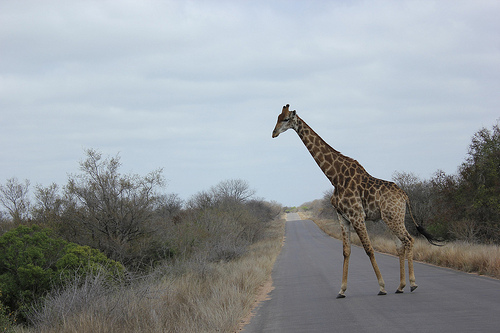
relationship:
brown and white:
[333, 160, 341, 173] [280, 123, 290, 130]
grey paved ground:
[285, 264, 325, 310] [270, 300, 491, 327]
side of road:
[409, 247, 498, 276] [288, 220, 496, 328]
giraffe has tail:
[267, 94, 454, 297] [403, 189, 458, 254]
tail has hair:
[403, 189, 458, 254] [421, 226, 452, 255]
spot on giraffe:
[340, 174, 352, 191] [267, 94, 454, 297]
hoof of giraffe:
[324, 276, 350, 302] [267, 94, 454, 297]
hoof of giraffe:
[370, 261, 387, 297] [267, 94, 454, 297]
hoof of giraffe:
[390, 270, 411, 298] [267, 94, 454, 297]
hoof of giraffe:
[406, 270, 431, 298] [267, 94, 454, 297]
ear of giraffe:
[288, 106, 302, 122] [267, 94, 454, 297]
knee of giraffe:
[334, 237, 356, 263] [267, 94, 454, 297]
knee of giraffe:
[357, 235, 386, 264] [267, 94, 454, 297]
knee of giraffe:
[391, 235, 407, 266] [267, 94, 454, 297]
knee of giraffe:
[404, 246, 419, 264] [267, 94, 454, 297]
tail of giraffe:
[403, 189, 458, 254] [267, 94, 454, 297]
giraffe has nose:
[267, 94, 454, 297] [271, 116, 284, 141]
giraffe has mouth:
[267, 94, 454, 297] [269, 129, 285, 146]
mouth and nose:
[269, 129, 285, 146] [271, 116, 284, 141]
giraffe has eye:
[267, 94, 454, 297] [282, 114, 293, 126]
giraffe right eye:
[267, 94, 454, 297] [282, 114, 293, 126]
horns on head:
[280, 96, 297, 112] [262, 85, 301, 140]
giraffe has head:
[267, 94, 454, 297] [262, 85, 301, 140]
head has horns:
[262, 85, 301, 140] [280, 96, 297, 112]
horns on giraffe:
[280, 96, 297, 112] [267, 94, 454, 297]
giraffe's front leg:
[267, 94, 454, 297] [348, 206, 393, 298]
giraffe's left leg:
[267, 94, 454, 297] [348, 206, 393, 298]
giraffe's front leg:
[267, 94, 454, 297] [330, 192, 362, 310]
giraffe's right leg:
[267, 94, 454, 297] [330, 192, 362, 310]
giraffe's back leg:
[267, 94, 454, 297] [403, 205, 425, 297]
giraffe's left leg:
[267, 94, 454, 297] [403, 205, 425, 297]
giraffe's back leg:
[267, 94, 454, 297] [387, 219, 410, 299]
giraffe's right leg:
[267, 94, 454, 297] [387, 219, 410, 299]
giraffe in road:
[267, 94, 454, 297] [288, 220, 496, 328]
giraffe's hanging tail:
[267, 94, 454, 297] [403, 189, 458, 254]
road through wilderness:
[288, 220, 496, 328] [45, 150, 322, 325]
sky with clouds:
[53, 13, 459, 86] [47, 12, 191, 112]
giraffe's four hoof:
[267, 94, 454, 297] [377, 290, 387, 297]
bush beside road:
[4, 220, 125, 321] [288, 220, 496, 328]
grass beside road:
[415, 237, 497, 272] [288, 220, 496, 328]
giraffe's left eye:
[267, 94, 454, 297] [282, 114, 293, 126]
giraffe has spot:
[267, 94, 454, 297] [340, 174, 352, 191]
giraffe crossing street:
[267, 94, 454, 297] [288, 220, 496, 328]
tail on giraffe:
[403, 189, 458, 254] [267, 94, 454, 297]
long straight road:
[283, 195, 335, 332] [288, 220, 496, 328]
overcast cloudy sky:
[68, 3, 253, 93] [53, 13, 459, 86]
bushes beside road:
[4, 220, 125, 321] [288, 220, 496, 328]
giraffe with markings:
[267, 94, 454, 297] [323, 156, 366, 206]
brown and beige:
[333, 160, 341, 173] [387, 202, 403, 220]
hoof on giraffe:
[377, 290, 387, 297] [267, 94, 454, 297]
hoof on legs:
[377, 290, 387, 297] [320, 217, 424, 294]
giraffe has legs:
[267, 94, 454, 297] [320, 217, 424, 294]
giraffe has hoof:
[267, 94, 454, 297] [377, 290, 387, 297]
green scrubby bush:
[5, 225, 76, 278] [4, 220, 125, 321]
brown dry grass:
[445, 243, 497, 277] [415, 237, 497, 272]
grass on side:
[415, 237, 497, 272] [409, 247, 498, 276]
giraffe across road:
[267, 94, 454, 297] [288, 220, 496, 328]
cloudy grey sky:
[69, 31, 214, 105] [53, 13, 459, 86]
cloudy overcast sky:
[69, 31, 214, 105] [53, 13, 459, 86]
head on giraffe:
[262, 85, 301, 140] [267, 94, 454, 297]